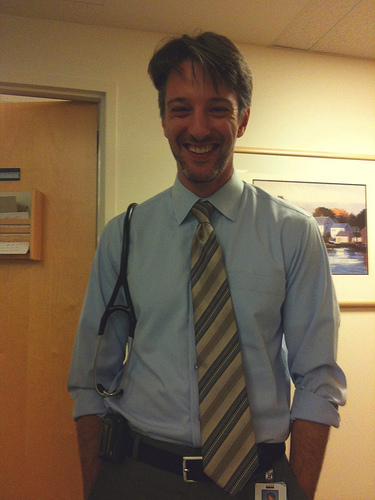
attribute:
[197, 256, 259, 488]
stripe — Grey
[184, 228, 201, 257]
stripe —  Grey 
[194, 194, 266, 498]
tie — gray, blue, stripes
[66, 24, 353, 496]
man — blue shirt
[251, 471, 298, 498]
card — identification, small 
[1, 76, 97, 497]
door — open 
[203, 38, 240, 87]
hair — short graying blond 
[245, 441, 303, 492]
pocket — left hand